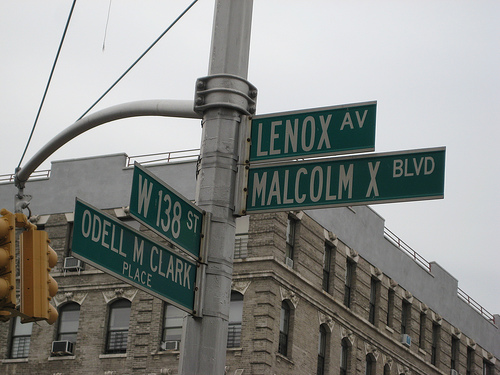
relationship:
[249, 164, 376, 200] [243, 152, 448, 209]
writing on sign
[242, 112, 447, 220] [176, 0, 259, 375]
signs on a post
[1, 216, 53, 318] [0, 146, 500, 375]
light near building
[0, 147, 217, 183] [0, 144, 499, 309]
fence on roof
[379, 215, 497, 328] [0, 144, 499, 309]
fence on roof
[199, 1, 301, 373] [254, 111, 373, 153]
post holding sign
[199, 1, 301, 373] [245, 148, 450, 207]
post holding sign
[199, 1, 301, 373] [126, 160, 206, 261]
post holding street sign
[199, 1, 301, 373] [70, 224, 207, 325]
post holding sign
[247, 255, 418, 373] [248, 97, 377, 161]
building behind sign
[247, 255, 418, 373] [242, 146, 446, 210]
building behind signs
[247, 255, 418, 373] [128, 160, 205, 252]
building behind street sign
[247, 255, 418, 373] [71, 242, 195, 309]
building behind street sign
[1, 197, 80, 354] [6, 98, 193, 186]
signal light hanging from arm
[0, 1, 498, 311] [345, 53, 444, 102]
sky in distance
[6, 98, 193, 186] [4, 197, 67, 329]
arm supports light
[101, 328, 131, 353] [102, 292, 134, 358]
bars on window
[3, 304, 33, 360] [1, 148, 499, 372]
window on building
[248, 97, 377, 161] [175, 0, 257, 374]
sign has pole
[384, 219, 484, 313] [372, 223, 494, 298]
railing on roof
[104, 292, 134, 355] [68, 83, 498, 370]
window on building